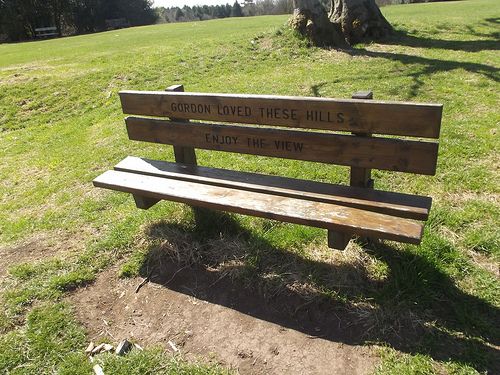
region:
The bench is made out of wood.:
[125, 82, 450, 262]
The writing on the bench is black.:
[162, 98, 352, 168]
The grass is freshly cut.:
[64, 29, 289, 85]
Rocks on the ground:
[66, 321, 178, 358]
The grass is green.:
[73, 31, 238, 78]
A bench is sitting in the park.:
[91, 89, 463, 290]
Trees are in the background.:
[178, 0, 295, 32]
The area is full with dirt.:
[130, 232, 420, 367]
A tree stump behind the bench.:
[284, 2, 403, 55]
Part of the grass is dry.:
[25, 120, 102, 236]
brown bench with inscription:
[111, 77, 445, 179]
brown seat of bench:
[94, 145, 439, 250]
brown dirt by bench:
[96, 259, 356, 356]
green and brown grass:
[8, 170, 87, 360]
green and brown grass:
[6, 50, 110, 157]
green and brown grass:
[157, 25, 279, 72]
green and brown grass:
[326, 50, 494, 82]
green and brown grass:
[393, 261, 488, 358]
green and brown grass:
[408, 12, 492, 91]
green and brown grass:
[458, 83, 490, 266]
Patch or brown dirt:
[65, 268, 189, 370]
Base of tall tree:
[262, 6, 407, 56]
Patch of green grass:
[0, 67, 97, 134]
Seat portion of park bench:
[96, 139, 224, 233]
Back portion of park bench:
[99, 81, 454, 177]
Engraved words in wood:
[164, 96, 356, 130]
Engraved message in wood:
[195, 128, 315, 162]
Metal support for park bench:
[335, 83, 387, 120]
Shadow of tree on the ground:
[377, 14, 489, 92]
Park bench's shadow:
[158, 273, 493, 370]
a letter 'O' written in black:
[175, 102, 187, 114]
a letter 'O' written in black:
[196, 102, 204, 114]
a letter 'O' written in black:
[221, 105, 231, 115]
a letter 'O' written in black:
[223, 135, 230, 144]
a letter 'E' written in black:
[236, 104, 245, 119]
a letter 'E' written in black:
[271, 105, 282, 120]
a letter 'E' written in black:
[289, 105, 299, 121]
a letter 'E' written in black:
[257, 137, 265, 149]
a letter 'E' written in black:
[282, 138, 294, 153]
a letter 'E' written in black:
[203, 129, 215, 146]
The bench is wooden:
[111, 63, 475, 263]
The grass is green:
[20, 86, 137, 252]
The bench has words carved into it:
[134, 80, 426, 213]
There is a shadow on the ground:
[227, 227, 464, 374]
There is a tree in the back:
[236, 7, 433, 109]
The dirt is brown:
[145, 287, 346, 374]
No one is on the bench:
[108, 84, 498, 278]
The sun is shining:
[74, 93, 278, 244]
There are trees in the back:
[160, 2, 283, 29]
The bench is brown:
[200, 130, 412, 241]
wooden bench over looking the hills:
[92, 80, 447, 252]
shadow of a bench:
[137, 208, 498, 373]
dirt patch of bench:
[68, 264, 374, 374]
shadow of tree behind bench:
[310, 44, 497, 104]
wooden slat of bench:
[89, 167, 425, 244]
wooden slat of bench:
[113, 153, 433, 222]